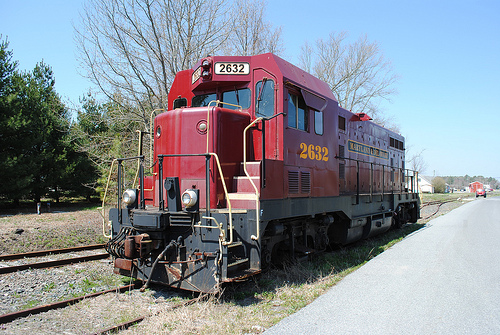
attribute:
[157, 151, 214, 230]
railing — for safety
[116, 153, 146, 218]
railing — for safety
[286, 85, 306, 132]
window — side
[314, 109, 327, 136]
window — side